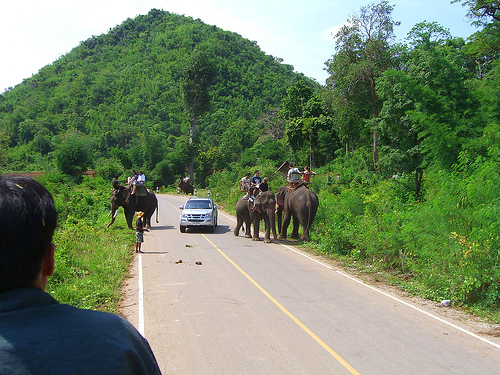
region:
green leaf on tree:
[114, 39, 155, 88]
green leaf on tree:
[79, 53, 116, 100]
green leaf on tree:
[42, 85, 73, 123]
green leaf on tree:
[9, 94, 42, 134]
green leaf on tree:
[69, 110, 109, 145]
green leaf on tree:
[223, 72, 262, 119]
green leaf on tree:
[259, 67, 286, 92]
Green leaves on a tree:
[442, 161, 495, 205]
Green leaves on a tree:
[406, 55, 476, 112]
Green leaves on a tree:
[331, 31, 399, 78]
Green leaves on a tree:
[318, 80, 400, 140]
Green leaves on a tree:
[321, 127, 403, 183]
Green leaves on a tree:
[247, 43, 327, 100]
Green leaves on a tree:
[93, 11, 207, 43]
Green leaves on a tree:
[50, 57, 162, 107]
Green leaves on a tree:
[28, 101, 115, 169]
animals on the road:
[70, 82, 371, 303]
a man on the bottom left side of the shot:
[0, 172, 171, 373]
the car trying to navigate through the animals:
[99, 143, 350, 269]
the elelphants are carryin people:
[237, 155, 323, 251]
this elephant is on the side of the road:
[90, 152, 165, 254]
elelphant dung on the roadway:
[163, 237, 215, 279]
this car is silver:
[169, 179, 233, 242]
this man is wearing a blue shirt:
[2, 164, 164, 368]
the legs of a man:
[129, 231, 153, 259]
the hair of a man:
[7, 156, 87, 288]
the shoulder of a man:
[54, 282, 186, 366]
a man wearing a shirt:
[2, 132, 199, 357]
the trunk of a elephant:
[259, 196, 299, 253]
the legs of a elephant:
[222, 208, 270, 244]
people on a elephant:
[229, 139, 287, 225]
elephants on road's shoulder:
[213, 156, 323, 261]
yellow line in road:
[177, 241, 317, 373]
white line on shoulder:
[288, 259, 486, 373]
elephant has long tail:
[295, 202, 320, 242]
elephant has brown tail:
[293, 209, 320, 240]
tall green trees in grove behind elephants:
[5, 14, 331, 184]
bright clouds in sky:
[169, 0, 343, 73]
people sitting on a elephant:
[234, 163, 276, 241]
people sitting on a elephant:
[100, 170, 162, 236]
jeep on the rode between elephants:
[183, 192, 222, 234]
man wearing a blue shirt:
[5, 288, 142, 373]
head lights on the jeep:
[181, 210, 211, 220]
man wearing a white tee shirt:
[133, 171, 148, 180]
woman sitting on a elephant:
[298, 163, 310, 184]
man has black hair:
[1, 167, 56, 286]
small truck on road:
[175, 189, 219, 236]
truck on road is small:
[175, 192, 219, 236]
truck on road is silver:
[175, 191, 217, 233]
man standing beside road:
[4, 171, 162, 373]